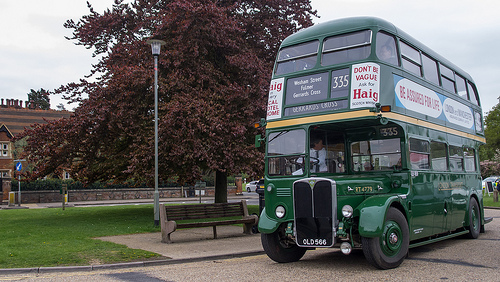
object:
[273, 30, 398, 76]
windows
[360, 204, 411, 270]
tire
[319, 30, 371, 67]
windows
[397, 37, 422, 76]
windows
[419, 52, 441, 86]
windows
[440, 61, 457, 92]
windows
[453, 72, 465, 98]
windows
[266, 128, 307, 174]
windows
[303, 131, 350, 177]
windows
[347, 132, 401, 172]
windows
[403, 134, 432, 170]
windows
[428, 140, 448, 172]
windows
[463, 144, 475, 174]
windows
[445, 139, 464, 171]
windows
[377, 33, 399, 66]
passenger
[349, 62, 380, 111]
sign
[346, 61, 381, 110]
advertisement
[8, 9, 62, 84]
cloud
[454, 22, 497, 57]
cloud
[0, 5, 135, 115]
sky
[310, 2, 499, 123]
sky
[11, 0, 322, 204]
tree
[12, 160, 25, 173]
flag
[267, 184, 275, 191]
light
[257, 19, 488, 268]
outlet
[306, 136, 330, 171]
driver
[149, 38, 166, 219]
light post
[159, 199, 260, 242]
bench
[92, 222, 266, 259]
sidewalk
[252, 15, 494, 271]
car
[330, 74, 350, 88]
numbers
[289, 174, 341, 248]
grill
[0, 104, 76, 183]
building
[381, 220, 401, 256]
hub cap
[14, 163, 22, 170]
arrow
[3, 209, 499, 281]
street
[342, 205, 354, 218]
light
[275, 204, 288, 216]
light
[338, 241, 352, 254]
light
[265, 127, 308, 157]
windows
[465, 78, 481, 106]
windows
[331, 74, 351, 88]
number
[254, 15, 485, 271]
bus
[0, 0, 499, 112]
clouds